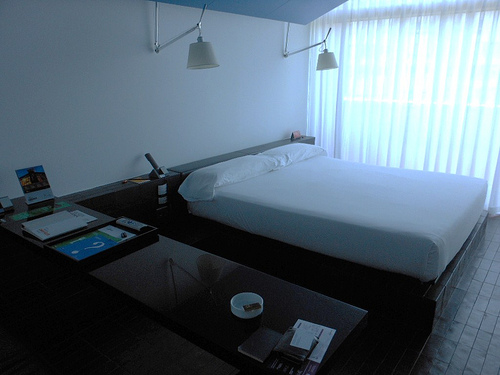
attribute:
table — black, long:
[2, 201, 366, 375]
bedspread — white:
[176, 142, 487, 286]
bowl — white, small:
[231, 292, 264, 318]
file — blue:
[54, 231, 116, 260]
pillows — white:
[177, 143, 330, 204]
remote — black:
[143, 153, 166, 177]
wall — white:
[1, 1, 312, 199]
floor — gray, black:
[1, 214, 499, 374]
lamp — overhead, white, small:
[153, 1, 218, 70]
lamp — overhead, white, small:
[284, 22, 339, 72]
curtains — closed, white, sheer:
[308, 1, 500, 215]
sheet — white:
[187, 155, 487, 282]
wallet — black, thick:
[273, 328, 317, 366]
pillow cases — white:
[177, 142, 325, 200]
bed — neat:
[185, 154, 486, 283]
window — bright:
[307, 1, 499, 214]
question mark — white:
[71, 238, 104, 257]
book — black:
[238, 325, 282, 362]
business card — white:
[289, 326, 317, 352]